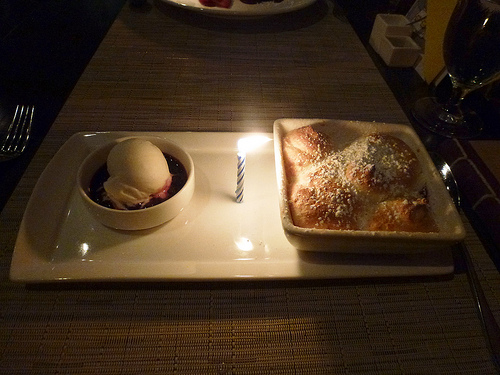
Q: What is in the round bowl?
A: Ice cream.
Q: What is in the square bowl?
A: A pastry.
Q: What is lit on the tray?
A: A candle.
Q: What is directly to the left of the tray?
A: A fork.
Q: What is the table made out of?
A: Wood.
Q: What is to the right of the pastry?
A: A spoon.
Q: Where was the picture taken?
A: In a restaurant.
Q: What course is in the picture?
A: Dessert.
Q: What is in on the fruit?
A: Ice cream.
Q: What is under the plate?
A: Table runner.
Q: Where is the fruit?
A: In bowl.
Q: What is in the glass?
A: Water.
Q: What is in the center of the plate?
A: Candle.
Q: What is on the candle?
A: Fire.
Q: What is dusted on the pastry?
A: Powdered sugar.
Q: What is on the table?
A: A white tray.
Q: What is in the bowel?
A: Berries and ice-cream.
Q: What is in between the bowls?
A: A candle.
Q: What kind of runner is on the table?
A: Bamboo.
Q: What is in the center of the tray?
A: Candle.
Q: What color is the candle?
A: White and blue.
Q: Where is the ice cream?
A: Bowl.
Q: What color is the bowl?
A: Cream.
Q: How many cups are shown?
A: One.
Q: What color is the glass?
A: Clear.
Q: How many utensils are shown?
A: Two.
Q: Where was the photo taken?
A: At an eating establishment.